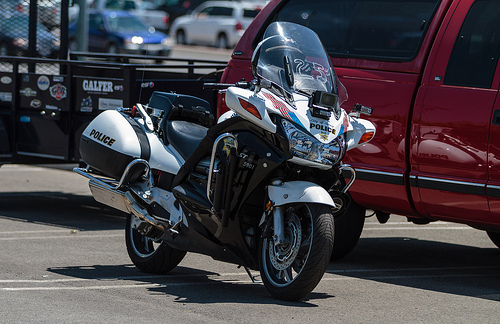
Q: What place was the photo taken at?
A: It was taken at the road.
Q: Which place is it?
A: It is a road.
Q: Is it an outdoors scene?
A: Yes, it is outdoors.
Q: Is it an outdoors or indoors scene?
A: It is outdoors.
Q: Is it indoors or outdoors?
A: It is outdoors.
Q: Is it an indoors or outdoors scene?
A: It is outdoors.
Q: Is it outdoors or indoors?
A: It is outdoors.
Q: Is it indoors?
A: No, it is outdoors.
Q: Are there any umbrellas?
A: No, there are no umbrellas.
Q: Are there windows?
A: Yes, there is a window.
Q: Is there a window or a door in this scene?
A: Yes, there is a window.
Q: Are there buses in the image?
A: No, there are no buses.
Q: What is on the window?
A: The number is on the window.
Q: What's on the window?
A: The number is on the window.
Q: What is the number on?
A: The number is on the window.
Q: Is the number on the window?
A: Yes, the number is on the window.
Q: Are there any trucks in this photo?
A: Yes, there is a truck.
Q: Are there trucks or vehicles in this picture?
A: Yes, there is a truck.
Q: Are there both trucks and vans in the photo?
A: No, there is a truck but no vans.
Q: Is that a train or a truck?
A: That is a truck.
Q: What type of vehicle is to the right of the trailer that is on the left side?
A: The vehicle is a truck.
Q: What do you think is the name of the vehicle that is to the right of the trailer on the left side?
A: The vehicle is a truck.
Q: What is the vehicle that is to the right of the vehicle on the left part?
A: The vehicle is a truck.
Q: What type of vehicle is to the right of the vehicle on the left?
A: The vehicle is a truck.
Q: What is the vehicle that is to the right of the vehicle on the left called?
A: The vehicle is a truck.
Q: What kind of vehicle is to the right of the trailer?
A: The vehicle is a truck.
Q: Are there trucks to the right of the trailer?
A: Yes, there is a truck to the right of the trailer.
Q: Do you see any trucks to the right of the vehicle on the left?
A: Yes, there is a truck to the right of the trailer.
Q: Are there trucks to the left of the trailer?
A: No, the truck is to the right of the trailer.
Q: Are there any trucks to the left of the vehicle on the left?
A: No, the truck is to the right of the trailer.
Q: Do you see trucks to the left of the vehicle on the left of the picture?
A: No, the truck is to the right of the trailer.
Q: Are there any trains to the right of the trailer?
A: No, there is a truck to the right of the trailer.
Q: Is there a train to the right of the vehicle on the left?
A: No, there is a truck to the right of the trailer.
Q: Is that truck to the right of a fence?
A: No, the truck is to the right of a trailer.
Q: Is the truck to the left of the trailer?
A: No, the truck is to the right of the trailer.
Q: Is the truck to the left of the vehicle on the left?
A: No, the truck is to the right of the trailer.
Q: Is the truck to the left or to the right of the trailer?
A: The truck is to the right of the trailer.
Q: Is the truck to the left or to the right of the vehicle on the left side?
A: The truck is to the right of the trailer.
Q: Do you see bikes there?
A: Yes, there is a bike.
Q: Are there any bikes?
A: Yes, there is a bike.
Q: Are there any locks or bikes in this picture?
A: Yes, there is a bike.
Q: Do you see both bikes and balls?
A: No, there is a bike but no balls.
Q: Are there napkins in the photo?
A: No, there are no napkins.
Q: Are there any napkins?
A: No, there are no napkins.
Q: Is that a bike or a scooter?
A: That is a bike.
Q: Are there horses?
A: No, there are no horses.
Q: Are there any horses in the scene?
A: No, there are no horses.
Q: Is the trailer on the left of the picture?
A: Yes, the trailer is on the left of the image.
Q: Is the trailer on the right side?
A: No, the trailer is on the left of the image.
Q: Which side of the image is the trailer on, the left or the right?
A: The trailer is on the left of the image.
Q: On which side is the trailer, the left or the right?
A: The trailer is on the left of the image.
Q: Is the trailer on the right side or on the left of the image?
A: The trailer is on the left of the image.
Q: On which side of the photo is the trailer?
A: The trailer is on the left of the image.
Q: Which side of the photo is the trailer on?
A: The trailer is on the left of the image.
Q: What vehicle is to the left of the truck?
A: The vehicle is a trailer.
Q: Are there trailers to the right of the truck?
A: No, the trailer is to the left of the truck.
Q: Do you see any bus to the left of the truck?
A: No, there is a trailer to the left of the truck.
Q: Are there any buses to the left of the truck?
A: No, there is a trailer to the left of the truck.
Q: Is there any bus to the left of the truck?
A: No, there is a trailer to the left of the truck.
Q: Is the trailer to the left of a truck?
A: Yes, the trailer is to the left of a truck.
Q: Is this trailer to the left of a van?
A: No, the trailer is to the left of a truck.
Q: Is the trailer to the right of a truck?
A: No, the trailer is to the left of a truck.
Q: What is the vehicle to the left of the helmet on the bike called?
A: The vehicle is a trailer.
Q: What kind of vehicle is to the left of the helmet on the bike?
A: The vehicle is a trailer.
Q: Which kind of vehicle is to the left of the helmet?
A: The vehicle is a trailer.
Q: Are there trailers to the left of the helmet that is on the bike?
A: Yes, there is a trailer to the left of the helmet.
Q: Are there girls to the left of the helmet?
A: No, there is a trailer to the left of the helmet.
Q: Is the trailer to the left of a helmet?
A: Yes, the trailer is to the left of a helmet.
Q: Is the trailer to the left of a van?
A: No, the trailer is to the left of a helmet.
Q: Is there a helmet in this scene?
A: Yes, there is a helmet.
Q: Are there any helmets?
A: Yes, there is a helmet.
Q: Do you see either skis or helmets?
A: Yes, there is a helmet.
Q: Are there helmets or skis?
A: Yes, there is a helmet.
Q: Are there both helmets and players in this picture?
A: No, there is a helmet but no players.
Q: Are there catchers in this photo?
A: No, there are no catchers.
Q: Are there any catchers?
A: No, there are no catchers.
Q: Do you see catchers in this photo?
A: No, there are no catchers.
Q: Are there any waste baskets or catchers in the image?
A: No, there are no catchers or waste baskets.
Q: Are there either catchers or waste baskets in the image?
A: No, there are no catchers or waste baskets.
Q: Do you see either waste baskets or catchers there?
A: No, there are no catchers or waste baskets.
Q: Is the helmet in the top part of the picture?
A: Yes, the helmet is in the top of the image.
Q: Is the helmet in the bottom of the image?
A: No, the helmet is in the top of the image.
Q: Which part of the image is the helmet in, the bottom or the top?
A: The helmet is in the top of the image.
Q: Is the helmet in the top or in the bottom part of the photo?
A: The helmet is in the top of the image.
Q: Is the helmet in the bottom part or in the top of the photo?
A: The helmet is in the top of the image.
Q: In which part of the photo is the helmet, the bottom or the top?
A: The helmet is in the top of the image.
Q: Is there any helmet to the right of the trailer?
A: Yes, there is a helmet to the right of the trailer.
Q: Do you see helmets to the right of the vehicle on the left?
A: Yes, there is a helmet to the right of the trailer.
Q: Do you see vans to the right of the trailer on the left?
A: No, there is a helmet to the right of the trailer.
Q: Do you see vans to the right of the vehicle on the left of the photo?
A: No, there is a helmet to the right of the trailer.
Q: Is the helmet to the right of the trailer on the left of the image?
A: Yes, the helmet is to the right of the trailer.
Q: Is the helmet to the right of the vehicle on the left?
A: Yes, the helmet is to the right of the trailer.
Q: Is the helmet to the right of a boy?
A: No, the helmet is to the right of the trailer.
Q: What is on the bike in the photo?
A: The helmet is on the bike.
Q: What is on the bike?
A: The helmet is on the bike.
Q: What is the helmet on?
A: The helmet is on the bike.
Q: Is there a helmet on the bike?
A: Yes, there is a helmet on the bike.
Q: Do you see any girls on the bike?
A: No, there is a helmet on the bike.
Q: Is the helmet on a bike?
A: Yes, the helmet is on a bike.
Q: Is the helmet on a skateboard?
A: No, the helmet is on a bike.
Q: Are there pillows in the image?
A: No, there are no pillows.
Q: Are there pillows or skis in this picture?
A: No, there are no pillows or skis.